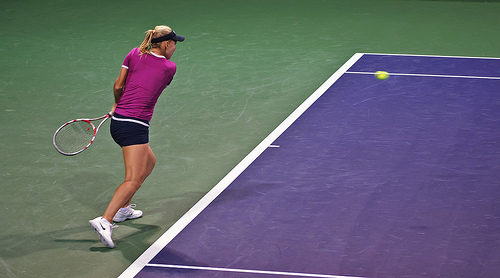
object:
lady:
[87, 22, 179, 250]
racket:
[52, 112, 105, 156]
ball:
[373, 69, 389, 81]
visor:
[173, 29, 186, 43]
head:
[150, 25, 177, 59]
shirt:
[115, 47, 179, 120]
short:
[108, 121, 149, 147]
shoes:
[90, 215, 118, 247]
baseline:
[111, 51, 365, 277]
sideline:
[358, 50, 496, 61]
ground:
[0, 0, 52, 276]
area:
[0, 0, 495, 277]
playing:
[10, 21, 396, 247]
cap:
[152, 31, 186, 43]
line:
[343, 68, 500, 78]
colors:
[65, 119, 92, 126]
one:
[99, 221, 107, 230]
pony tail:
[139, 28, 154, 58]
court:
[9, 6, 499, 278]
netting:
[63, 128, 84, 146]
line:
[270, 144, 280, 149]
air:
[0, 0, 500, 278]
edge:
[345, 51, 421, 64]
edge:
[107, 118, 150, 126]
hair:
[136, 26, 174, 58]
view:
[0, 0, 500, 278]